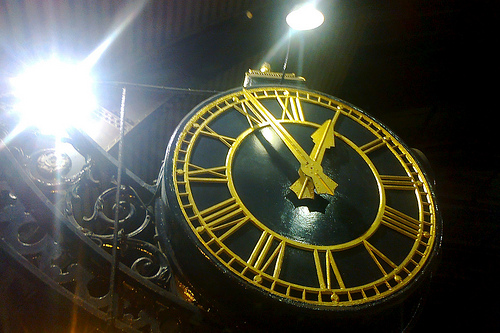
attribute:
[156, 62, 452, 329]
clock — large, black, yellow, round, dark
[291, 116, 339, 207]
hand — yellow, gold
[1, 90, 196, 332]
mount — iron, large, steel, metal, decorative, black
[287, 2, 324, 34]
light — on, bright, shiny, white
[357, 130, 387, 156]
number — gold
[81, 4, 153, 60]
ray — white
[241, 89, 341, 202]
hand — yellow, gold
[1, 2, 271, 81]
roof — iron